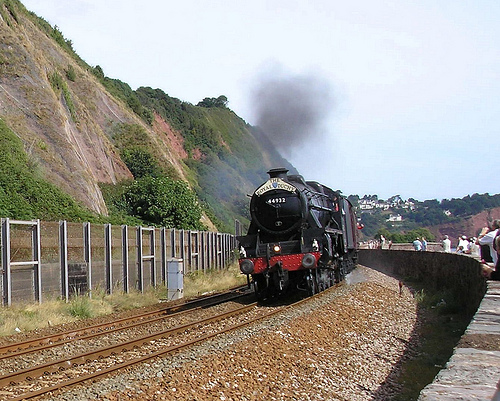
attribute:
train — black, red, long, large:
[239, 161, 376, 298]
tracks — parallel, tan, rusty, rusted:
[152, 324, 228, 354]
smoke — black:
[257, 86, 317, 143]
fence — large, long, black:
[85, 231, 135, 298]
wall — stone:
[4, 218, 40, 308]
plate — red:
[250, 254, 312, 268]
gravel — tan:
[221, 346, 264, 377]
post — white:
[80, 229, 93, 287]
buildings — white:
[371, 193, 400, 207]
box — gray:
[160, 257, 186, 297]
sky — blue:
[440, 113, 464, 153]